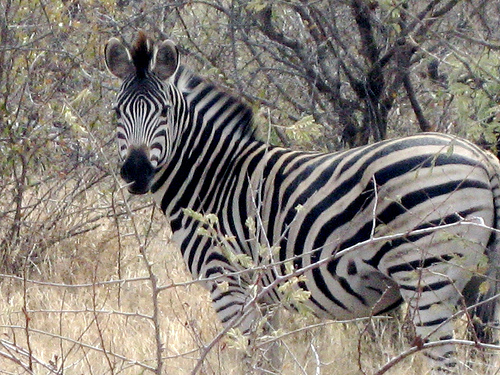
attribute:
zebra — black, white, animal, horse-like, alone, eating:
[102, 26, 497, 375]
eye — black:
[112, 103, 123, 118]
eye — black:
[159, 103, 170, 116]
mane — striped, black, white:
[130, 30, 264, 141]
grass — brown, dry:
[1, 182, 495, 372]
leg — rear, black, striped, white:
[386, 265, 459, 373]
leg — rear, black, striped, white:
[475, 260, 499, 345]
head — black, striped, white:
[100, 38, 181, 202]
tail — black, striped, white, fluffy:
[484, 165, 499, 250]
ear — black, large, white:
[101, 35, 136, 82]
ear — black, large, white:
[150, 39, 181, 87]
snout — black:
[118, 152, 156, 195]